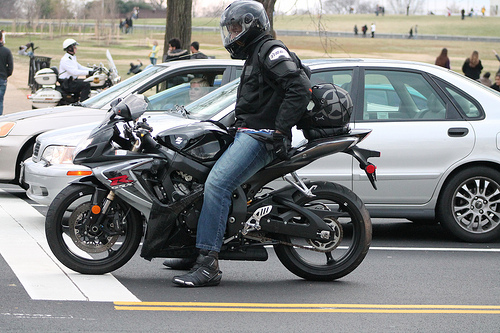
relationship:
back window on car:
[362, 69, 448, 118] [23, 59, 497, 241]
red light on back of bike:
[364, 163, 374, 173] [44, 82, 381, 279]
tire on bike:
[42, 173, 142, 271] [37, 98, 388, 285]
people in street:
[345, 15, 422, 37] [0, 8, 498, 43]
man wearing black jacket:
[161, 0, 314, 287] [236, 39, 311, 130]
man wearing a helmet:
[159, 7, 310, 290] [219, 1, 275, 58]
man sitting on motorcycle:
[161, 0, 314, 287] [26, 47, 403, 283]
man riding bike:
[159, 7, 310, 290] [44, 82, 381, 279]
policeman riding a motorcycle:
[57, 38, 102, 105] [23, 33, 108, 109]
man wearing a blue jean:
[159, 7, 310, 290] [194, 127, 254, 262]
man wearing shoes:
[161, 0, 314, 287] [167, 254, 225, 285]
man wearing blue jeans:
[161, 0, 314, 287] [190, 127, 282, 254]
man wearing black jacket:
[161, 0, 314, 287] [233, 35, 312, 134]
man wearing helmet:
[161, 0, 314, 287] [218, 1, 273, 62]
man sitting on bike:
[161, 0, 314, 287] [44, 82, 381, 279]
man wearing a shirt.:
[161, 0, 314, 287] [56, 55, 90, 81]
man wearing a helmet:
[161, 0, 314, 287] [205, 6, 323, 70]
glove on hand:
[253, 126, 283, 151] [266, 101, 296, 188]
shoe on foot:
[166, 255, 226, 287] [158, 222, 266, 320]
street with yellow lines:
[143, 241, 484, 331] [109, 296, 498, 318]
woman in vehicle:
[172, 54, 216, 99] [20, 0, 484, 172]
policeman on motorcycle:
[16, 28, 130, 109] [54, 65, 473, 290]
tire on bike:
[272, 177, 374, 281] [44, 82, 381, 279]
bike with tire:
[44, 82, 381, 279] [268, 181, 371, 280]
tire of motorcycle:
[42, 175, 146, 274] [51, 103, 404, 297]